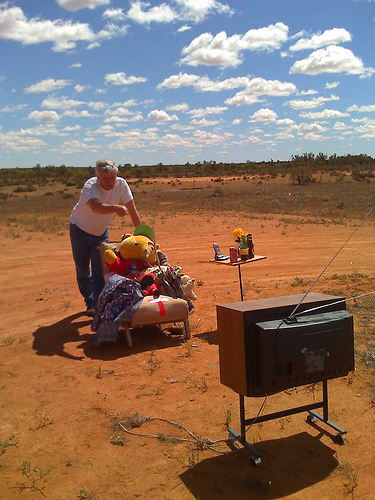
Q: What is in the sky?
A: Many clouds.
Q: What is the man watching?
A: A TV.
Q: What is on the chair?
A: A teddy bear.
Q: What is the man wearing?
A: A white shirt.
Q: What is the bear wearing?
A: A red shirt.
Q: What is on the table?
A: A phone.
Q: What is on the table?
A: Bottles.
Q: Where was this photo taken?
A: In a field.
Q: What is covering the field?
A: Dirt.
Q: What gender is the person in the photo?
A: Male.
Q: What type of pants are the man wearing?
A: Blue jeans.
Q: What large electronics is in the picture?
A: A TV.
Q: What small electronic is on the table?
A: A phone.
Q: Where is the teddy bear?
A: In the chair.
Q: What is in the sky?
A: Clouds.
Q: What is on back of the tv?
A: Antenna.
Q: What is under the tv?
A: A shadow.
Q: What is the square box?
A: Old t.v.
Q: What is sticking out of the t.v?
A: Antenna.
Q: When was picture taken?
A: Daytime.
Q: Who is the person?
A: Director.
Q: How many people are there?
A: One.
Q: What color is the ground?
A: Brown.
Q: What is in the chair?
A: Bear.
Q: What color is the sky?
A: Blue.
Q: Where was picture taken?
A: In the desert.